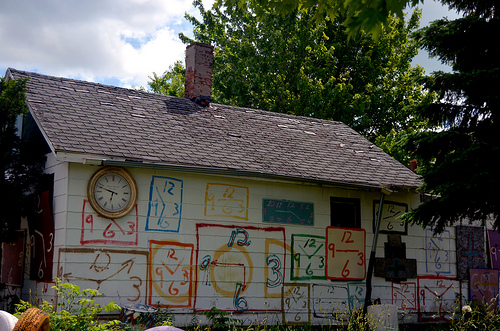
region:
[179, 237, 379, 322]
the wall is full of art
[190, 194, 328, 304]
the wall is full of art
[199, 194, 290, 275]
the wall is full of art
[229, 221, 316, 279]
the wall is full of art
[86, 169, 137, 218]
clock graphic on side of a white house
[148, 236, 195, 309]
orange clock drawing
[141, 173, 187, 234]
blue square clock drawing on a house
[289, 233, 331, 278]
green clock drawing on a house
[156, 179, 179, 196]
the number twelve drawn on the side of a house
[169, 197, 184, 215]
the number three drawn in blue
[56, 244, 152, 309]
brown square clock drawing on the side of a house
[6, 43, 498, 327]
an abandoned house with colorful clock drawings all over it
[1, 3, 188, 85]
white clouds in a blue sky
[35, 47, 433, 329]
house covered with drawings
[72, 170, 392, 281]
house covered with drawings of clocks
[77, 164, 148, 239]
circular clock drawn on side of hosue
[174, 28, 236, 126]
chimney on top of house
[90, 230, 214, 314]
orange and red clock drawn on side of house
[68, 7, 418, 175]
tree growing behind house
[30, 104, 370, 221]
wooden roof on top of hosue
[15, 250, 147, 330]
small green bushes growing by house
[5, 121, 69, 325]
entrance to house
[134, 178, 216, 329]
square clocks drawn on house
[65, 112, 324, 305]
this is a house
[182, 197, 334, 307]
the wall is drawn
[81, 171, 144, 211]
this is a clock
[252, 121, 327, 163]
the roof is made of bicks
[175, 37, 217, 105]
this is a chimney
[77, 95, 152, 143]
the roof is brown in color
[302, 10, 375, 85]
a tree is beside the house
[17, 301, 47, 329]
the wheel is old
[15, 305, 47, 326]
the wheel is brown in color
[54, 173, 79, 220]
the wall is white in color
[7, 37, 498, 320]
a white shingled house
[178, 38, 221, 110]
a tall brick chimney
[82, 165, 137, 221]
an outdoor wall clock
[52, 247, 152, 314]
a piece of clock graffiti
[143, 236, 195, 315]
a piece of clock graffiti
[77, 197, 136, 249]
a piece of clock graffiti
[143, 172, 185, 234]
a piece of clock graffiti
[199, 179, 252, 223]
a piece of clock graffiti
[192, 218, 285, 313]
a piece of clock graffiti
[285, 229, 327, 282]
a piece of clock graffiti